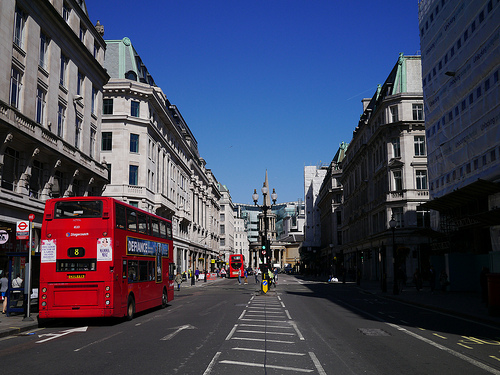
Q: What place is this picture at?
A: It is at the road.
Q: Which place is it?
A: It is a road.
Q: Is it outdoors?
A: Yes, it is outdoors.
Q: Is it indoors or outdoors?
A: It is outdoors.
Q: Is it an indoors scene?
A: No, it is outdoors.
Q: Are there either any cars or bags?
A: No, there are no cars or bags.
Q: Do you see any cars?
A: No, there are no cars.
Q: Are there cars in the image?
A: No, there are no cars.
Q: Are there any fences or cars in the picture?
A: No, there are no cars or fences.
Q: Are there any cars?
A: No, there are no cars.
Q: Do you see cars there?
A: No, there are no cars.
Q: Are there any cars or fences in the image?
A: No, there are no cars or fences.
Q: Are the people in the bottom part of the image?
A: Yes, the people are in the bottom of the image.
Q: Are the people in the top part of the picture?
A: No, the people are in the bottom of the image.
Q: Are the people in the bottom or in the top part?
A: The people are in the bottom of the image.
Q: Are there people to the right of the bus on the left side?
A: Yes, there are people to the right of the bus.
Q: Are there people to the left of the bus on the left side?
A: No, the people are to the right of the bus.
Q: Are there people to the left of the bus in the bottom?
A: Yes, there are people to the left of the bus.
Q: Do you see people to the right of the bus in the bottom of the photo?
A: No, the people are to the left of the bus.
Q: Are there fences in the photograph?
A: No, there are no fences.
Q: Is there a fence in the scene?
A: No, there are no fences.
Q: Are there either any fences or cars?
A: No, there are no fences or cars.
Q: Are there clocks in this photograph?
A: No, there are no clocks.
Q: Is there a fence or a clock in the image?
A: No, there are no clocks or fences.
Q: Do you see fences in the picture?
A: No, there are no fences.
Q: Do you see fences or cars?
A: No, there are no fences or cars.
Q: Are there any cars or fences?
A: No, there are no fences or cars.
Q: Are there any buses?
A: Yes, there is a bus.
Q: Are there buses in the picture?
A: Yes, there is a bus.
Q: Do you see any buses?
A: Yes, there is a bus.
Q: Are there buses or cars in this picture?
A: Yes, there is a bus.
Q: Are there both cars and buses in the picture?
A: No, there is a bus but no cars.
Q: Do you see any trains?
A: No, there are no trains.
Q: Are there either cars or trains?
A: No, there are no trains or cars.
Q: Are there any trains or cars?
A: No, there are no trains or cars.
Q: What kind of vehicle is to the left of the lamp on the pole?
A: The vehicle is a bus.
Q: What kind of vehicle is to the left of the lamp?
A: The vehicle is a bus.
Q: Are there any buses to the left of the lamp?
A: Yes, there is a bus to the left of the lamp.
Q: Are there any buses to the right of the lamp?
A: No, the bus is to the left of the lamp.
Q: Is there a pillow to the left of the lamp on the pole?
A: No, there is a bus to the left of the lamp.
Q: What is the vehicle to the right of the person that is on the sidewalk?
A: The vehicle is a bus.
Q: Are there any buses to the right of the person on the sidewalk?
A: Yes, there is a bus to the right of the person.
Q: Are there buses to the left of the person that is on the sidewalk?
A: No, the bus is to the right of the person.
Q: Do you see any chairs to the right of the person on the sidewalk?
A: No, there is a bus to the right of the person.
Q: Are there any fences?
A: No, there are no fences.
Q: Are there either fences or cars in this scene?
A: No, there are no fences or cars.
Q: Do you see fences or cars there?
A: No, there are no fences or cars.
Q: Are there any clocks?
A: No, there are no clocks.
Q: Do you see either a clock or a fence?
A: No, there are no clocks or fences.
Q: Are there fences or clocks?
A: No, there are no clocks or fences.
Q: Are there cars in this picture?
A: No, there are no cars.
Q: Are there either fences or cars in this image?
A: No, there are no cars or fences.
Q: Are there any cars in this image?
A: No, there are no cars.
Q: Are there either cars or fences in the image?
A: No, there are no cars or fences.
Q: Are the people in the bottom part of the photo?
A: Yes, the people are in the bottom of the image.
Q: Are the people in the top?
A: No, the people are in the bottom of the image.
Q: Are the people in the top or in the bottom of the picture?
A: The people are in the bottom of the image.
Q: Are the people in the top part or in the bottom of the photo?
A: The people are in the bottom of the image.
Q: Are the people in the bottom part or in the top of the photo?
A: The people are in the bottom of the image.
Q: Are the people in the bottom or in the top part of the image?
A: The people are in the bottom of the image.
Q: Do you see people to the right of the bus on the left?
A: Yes, there are people to the right of the bus.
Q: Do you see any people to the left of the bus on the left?
A: No, the people are to the right of the bus.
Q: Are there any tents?
A: No, there are no tents.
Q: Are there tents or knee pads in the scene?
A: No, there are no tents or knee pads.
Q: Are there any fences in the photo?
A: No, there are no fences.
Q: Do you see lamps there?
A: Yes, there is a lamp.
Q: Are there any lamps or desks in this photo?
A: Yes, there is a lamp.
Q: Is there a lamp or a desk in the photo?
A: Yes, there is a lamp.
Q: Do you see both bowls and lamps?
A: No, there is a lamp but no bowls.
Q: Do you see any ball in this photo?
A: No, there are no balls.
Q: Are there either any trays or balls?
A: No, there are no balls or trays.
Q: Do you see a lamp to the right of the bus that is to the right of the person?
A: Yes, there is a lamp to the right of the bus.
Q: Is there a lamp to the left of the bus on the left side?
A: No, the lamp is to the right of the bus.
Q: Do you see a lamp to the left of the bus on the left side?
A: No, the lamp is to the right of the bus.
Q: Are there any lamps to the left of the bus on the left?
A: No, the lamp is to the right of the bus.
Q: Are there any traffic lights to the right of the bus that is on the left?
A: No, there is a lamp to the right of the bus.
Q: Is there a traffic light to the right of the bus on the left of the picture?
A: No, there is a lamp to the right of the bus.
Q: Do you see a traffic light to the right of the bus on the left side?
A: No, there is a lamp to the right of the bus.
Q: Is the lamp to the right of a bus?
A: Yes, the lamp is to the right of a bus.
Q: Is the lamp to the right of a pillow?
A: No, the lamp is to the right of a bus.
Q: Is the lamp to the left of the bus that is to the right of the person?
A: No, the lamp is to the right of the bus.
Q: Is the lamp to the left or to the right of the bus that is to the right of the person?
A: The lamp is to the right of the bus.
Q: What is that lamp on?
A: The lamp is on the pole.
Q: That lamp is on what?
A: The lamp is on the pole.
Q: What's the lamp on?
A: The lamp is on the pole.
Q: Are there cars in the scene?
A: No, there are no cars.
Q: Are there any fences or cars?
A: No, there are no cars or fences.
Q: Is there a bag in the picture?
A: No, there are no bags.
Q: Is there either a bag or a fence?
A: No, there are no bags or fences.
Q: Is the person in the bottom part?
A: Yes, the person is in the bottom of the image.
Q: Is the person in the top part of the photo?
A: No, the person is in the bottom of the image.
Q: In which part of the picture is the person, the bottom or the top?
A: The person is in the bottom of the image.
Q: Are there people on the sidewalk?
A: Yes, there is a person on the sidewalk.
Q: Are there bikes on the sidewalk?
A: No, there is a person on the sidewalk.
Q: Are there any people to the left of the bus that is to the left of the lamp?
A: Yes, there is a person to the left of the bus.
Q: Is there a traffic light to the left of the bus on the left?
A: No, there is a person to the left of the bus.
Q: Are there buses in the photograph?
A: Yes, there is a bus.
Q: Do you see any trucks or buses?
A: Yes, there is a bus.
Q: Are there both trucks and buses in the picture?
A: No, there is a bus but no trucks.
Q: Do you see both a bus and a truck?
A: No, there is a bus but no trucks.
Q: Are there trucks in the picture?
A: No, there are no trucks.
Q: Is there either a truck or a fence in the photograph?
A: No, there are no trucks or fences.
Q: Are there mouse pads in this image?
A: No, there are no mouse pads.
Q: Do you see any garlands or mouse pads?
A: No, there are no mouse pads or garlands.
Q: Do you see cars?
A: No, there are no cars.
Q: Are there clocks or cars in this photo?
A: No, there are no cars or clocks.